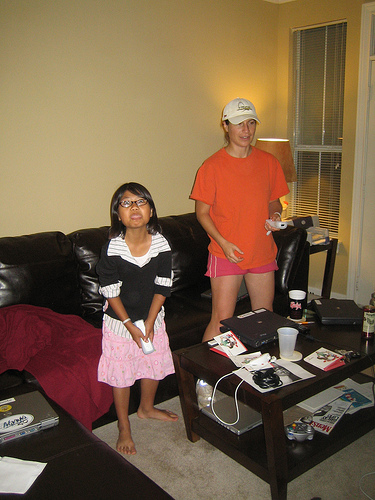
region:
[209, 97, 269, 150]
A woman in a white hat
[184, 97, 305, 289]
A woman playing Wii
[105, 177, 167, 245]
A child with black hair and glasses sticking out her tongue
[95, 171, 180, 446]
A young girl playing Wii and sticking out her tongue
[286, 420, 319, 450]
A game cube controller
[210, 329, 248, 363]
A Wii game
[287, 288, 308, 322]
A black and white plastic cup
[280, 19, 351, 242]
A window with blinds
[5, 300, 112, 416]
A red blanket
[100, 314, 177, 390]
A pink skirt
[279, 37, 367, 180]
a window with open blinds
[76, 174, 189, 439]
a girl holding a WII controller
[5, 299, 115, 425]
a red blanket on the sofa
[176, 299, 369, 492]
A brown coffee table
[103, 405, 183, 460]
bare feel on the carpet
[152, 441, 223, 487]
tan carpet covering the floor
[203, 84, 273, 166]
A woman wearing a cap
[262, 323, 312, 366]
a plastic cup on the table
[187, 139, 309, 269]
an orange t-shirt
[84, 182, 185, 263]
A girl wearing glasses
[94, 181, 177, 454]
Young girl sticking out tongue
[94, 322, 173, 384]
Pink dress on young girl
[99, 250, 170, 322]
Dark top on young girl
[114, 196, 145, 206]
Glasses on young girl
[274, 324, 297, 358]
Plastic cup on table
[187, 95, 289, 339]
Woman holding video game controller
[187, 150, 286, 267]
Orange shirt on a woman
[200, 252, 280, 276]
Pink shorts on a lady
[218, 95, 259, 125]
White hat on a lady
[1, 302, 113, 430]
Burgundy bedspread on black couch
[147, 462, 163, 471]
The floor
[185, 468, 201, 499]
The floor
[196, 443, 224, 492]
The floor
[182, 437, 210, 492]
The floor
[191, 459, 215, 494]
The floor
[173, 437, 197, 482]
The floor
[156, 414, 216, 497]
The floor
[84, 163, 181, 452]
young lady with dark brown hair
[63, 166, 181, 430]
girl wearing brown rim glasses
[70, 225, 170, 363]
girl wearing black and white short sleeve shirt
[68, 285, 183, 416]
girl wearing pink floral skirt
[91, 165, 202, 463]
girl wearing no shoes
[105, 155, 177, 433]
girl holding game controller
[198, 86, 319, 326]
girl wearing white ball cap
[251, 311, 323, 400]
clear plastic cup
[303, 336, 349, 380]
card lying on brown table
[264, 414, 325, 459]
gray game controller lying on table